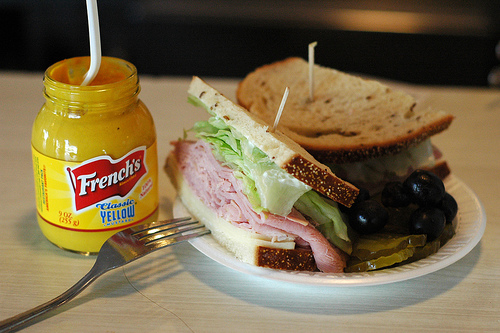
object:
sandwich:
[161, 56, 457, 274]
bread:
[236, 56, 456, 165]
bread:
[187, 73, 360, 208]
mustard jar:
[29, 56, 157, 255]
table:
[0, 73, 500, 333]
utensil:
[79, 0, 100, 88]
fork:
[0, 215, 211, 333]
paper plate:
[171, 173, 486, 287]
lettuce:
[185, 96, 353, 256]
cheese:
[282, 207, 309, 227]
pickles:
[346, 233, 441, 272]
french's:
[77, 159, 141, 196]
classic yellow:
[49, 181, 67, 204]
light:
[138, 222, 177, 248]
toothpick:
[308, 42, 319, 101]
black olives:
[341, 169, 458, 242]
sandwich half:
[162, 75, 359, 273]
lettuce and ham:
[168, 95, 352, 273]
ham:
[168, 131, 344, 274]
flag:
[66, 145, 147, 212]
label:
[30, 142, 158, 232]